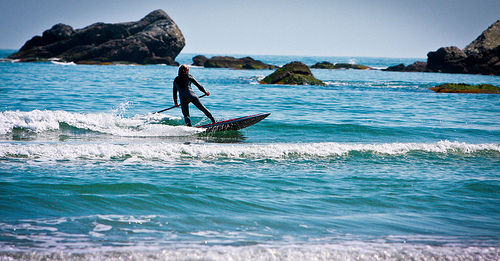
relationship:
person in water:
[167, 58, 216, 129] [1, 49, 494, 259]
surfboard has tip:
[200, 105, 270, 133] [255, 108, 272, 121]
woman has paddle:
[162, 66, 222, 126] [152, 90, 209, 117]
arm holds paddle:
[189, 74, 212, 95] [197, 93, 207, 98]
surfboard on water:
[200, 105, 265, 133] [114, 83, 372, 190]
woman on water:
[0, 65, 498, 170] [100, 68, 330, 178]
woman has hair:
[150, 66, 227, 109] [173, 60, 194, 78]